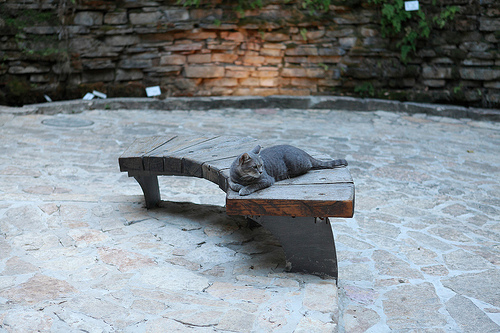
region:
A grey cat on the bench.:
[222, 141, 347, 200]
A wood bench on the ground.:
[116, 126, 363, 281]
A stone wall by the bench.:
[0, 1, 499, 123]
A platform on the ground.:
[1, 171, 378, 331]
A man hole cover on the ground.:
[37, 105, 95, 140]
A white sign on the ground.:
[138, 81, 166, 100]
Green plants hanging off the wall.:
[0, 3, 497, 50]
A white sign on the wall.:
[385, 0, 432, 32]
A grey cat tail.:
[303, 152, 355, 177]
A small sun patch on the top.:
[172, 28, 312, 103]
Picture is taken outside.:
[35, 24, 480, 308]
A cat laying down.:
[228, 133, 393, 188]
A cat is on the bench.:
[206, 105, 344, 217]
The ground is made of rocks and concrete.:
[367, 131, 465, 327]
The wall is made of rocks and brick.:
[107, 22, 413, 94]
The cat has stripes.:
[225, 137, 360, 182]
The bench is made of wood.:
[120, 122, 372, 225]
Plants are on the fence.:
[347, 7, 477, 72]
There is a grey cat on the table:
[208, 103, 368, 218]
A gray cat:
[224, 140, 350, 197]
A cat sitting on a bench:
[119, 127, 360, 275]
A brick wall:
[5, 0, 498, 96]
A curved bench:
[117, 128, 356, 274]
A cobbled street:
[360, 124, 495, 276]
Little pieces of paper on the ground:
[50, 65, 195, 112]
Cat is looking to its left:
[227, 142, 349, 196]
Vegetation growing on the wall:
[376, 0, 464, 65]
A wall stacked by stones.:
[96, 2, 394, 94]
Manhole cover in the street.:
[35, 108, 99, 132]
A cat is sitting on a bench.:
[217, 127, 367, 228]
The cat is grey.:
[216, 140, 366, 211]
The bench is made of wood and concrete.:
[100, 118, 371, 288]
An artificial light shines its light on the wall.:
[154, 21, 373, 132]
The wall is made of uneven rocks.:
[8, 1, 239, 89]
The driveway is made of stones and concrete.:
[371, 164, 498, 311]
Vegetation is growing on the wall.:
[347, 1, 499, 78]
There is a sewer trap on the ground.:
[36, 105, 122, 142]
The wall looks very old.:
[3, 0, 456, 84]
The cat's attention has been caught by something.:
[215, 136, 362, 203]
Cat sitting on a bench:
[212, 135, 327, 205]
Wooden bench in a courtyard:
[120, 120, 365, 280]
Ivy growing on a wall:
[330, 0, 495, 70]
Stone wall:
[115, 0, 295, 85]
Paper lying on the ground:
[72, 75, 167, 110]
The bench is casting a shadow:
[120, 192, 332, 288]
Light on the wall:
[160, 26, 340, 111]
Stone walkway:
[353, 146, 497, 328]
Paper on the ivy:
[373, 0, 443, 25]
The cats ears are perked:
[219, 140, 279, 207]